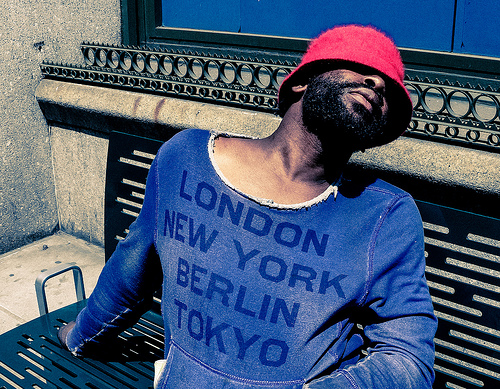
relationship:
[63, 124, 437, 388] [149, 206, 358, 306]
shirt says new york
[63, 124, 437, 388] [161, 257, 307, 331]
shirt says berlin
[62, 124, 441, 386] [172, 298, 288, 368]
shirt says tokyo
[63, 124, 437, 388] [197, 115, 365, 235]
shirt has neck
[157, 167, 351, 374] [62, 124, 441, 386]
text on shirt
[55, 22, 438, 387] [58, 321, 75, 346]
man has hand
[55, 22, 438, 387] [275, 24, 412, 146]
man wears hat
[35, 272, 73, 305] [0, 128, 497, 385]
handle on bench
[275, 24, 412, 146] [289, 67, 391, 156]
hat on head